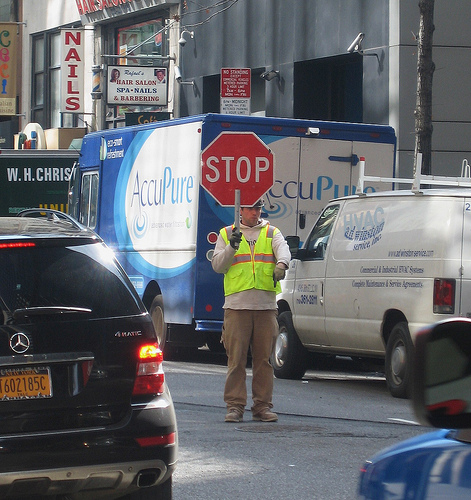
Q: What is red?
A: Sign.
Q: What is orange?
A: License plate.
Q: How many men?
A: One.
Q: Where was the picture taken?
A: City.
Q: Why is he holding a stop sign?
A: To stop traffic.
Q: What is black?
A: Car.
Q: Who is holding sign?
A: Man.